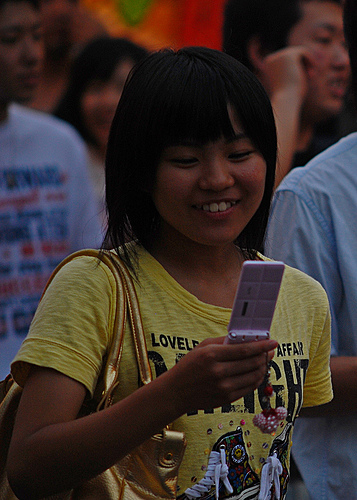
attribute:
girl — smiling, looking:
[11, 44, 335, 499]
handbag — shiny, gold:
[0, 248, 187, 499]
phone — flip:
[224, 261, 287, 343]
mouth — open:
[189, 197, 241, 219]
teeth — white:
[196, 203, 236, 212]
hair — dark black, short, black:
[91, 45, 277, 287]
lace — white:
[181, 449, 236, 498]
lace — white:
[256, 453, 283, 500]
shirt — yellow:
[9, 239, 335, 500]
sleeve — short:
[298, 307, 334, 409]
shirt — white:
[2, 102, 102, 380]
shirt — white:
[90, 155, 135, 248]